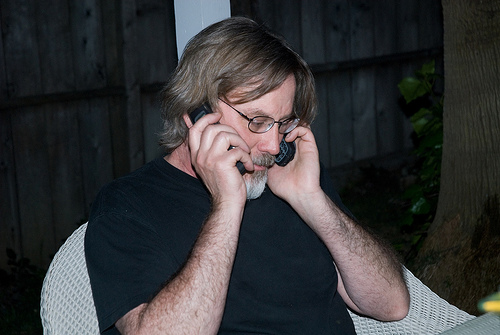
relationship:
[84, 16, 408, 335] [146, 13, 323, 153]
man has hair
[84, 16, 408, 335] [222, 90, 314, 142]
man has glasses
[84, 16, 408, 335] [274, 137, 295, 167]
man holds cell phone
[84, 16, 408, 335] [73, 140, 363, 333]
man has shirt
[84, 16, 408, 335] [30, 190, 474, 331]
man sits in chair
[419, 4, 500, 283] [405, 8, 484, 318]
tree of tree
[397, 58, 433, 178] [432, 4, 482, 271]
leaves behind tree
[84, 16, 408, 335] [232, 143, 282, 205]
man has beard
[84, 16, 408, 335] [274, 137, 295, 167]
man using two cell phone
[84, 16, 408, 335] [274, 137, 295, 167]
man talking on cell phone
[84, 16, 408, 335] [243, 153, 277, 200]
man has beard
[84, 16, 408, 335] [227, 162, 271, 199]
man has beard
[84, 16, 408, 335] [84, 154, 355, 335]
man wearing a shirt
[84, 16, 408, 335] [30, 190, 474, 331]
man sitting on chair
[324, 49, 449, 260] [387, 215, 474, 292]
plants on ground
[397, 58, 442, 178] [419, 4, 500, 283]
leaves are behind tree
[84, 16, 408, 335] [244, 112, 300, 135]
man has on eyeglasses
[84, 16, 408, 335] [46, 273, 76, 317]
man sitting on a chair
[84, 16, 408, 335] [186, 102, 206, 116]
man holding cell phone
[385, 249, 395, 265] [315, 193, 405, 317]
hair on mans arm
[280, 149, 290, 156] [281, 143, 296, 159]
buttons are on a cell phone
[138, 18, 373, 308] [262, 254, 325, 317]
man has on black t-shirt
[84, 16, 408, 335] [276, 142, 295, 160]
man on phone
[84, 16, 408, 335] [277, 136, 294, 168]
man holds cellphone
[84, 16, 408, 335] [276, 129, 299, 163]
man holds cellphone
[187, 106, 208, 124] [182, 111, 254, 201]
cell phone in hand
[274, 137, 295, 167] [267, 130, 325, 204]
cell phone in hand